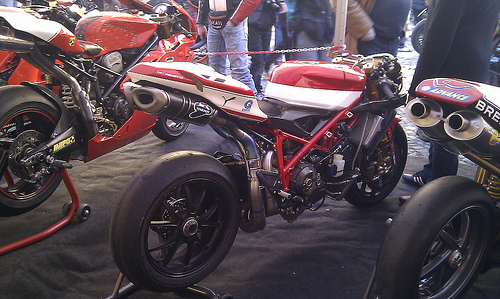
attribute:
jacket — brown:
[329, 1, 374, 51]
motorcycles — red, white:
[3, 8, 438, 270]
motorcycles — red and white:
[4, 5, 492, 297]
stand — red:
[50, 158, 98, 226]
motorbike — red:
[104, 44, 409, 291]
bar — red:
[8, 177, 73, 262]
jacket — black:
[413, 2, 498, 92]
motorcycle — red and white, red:
[112, 48, 404, 291]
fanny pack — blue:
[203, 15, 228, 33]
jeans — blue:
[200, 7, 265, 97]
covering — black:
[0, 154, 500, 296]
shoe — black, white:
[398, 167, 432, 188]